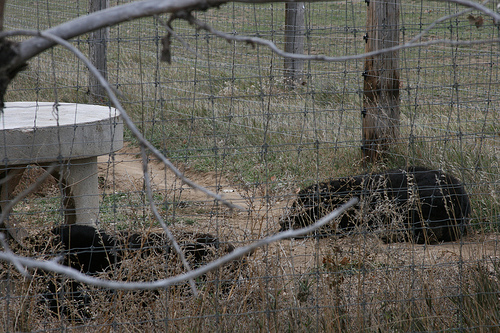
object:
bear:
[276, 164, 473, 246]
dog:
[277, 164, 473, 246]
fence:
[0, 0, 500, 333]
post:
[358, 0, 408, 170]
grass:
[0, 0, 499, 237]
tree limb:
[0, 195, 360, 291]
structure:
[0, 99, 128, 231]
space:
[6, 164, 80, 252]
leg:
[58, 157, 102, 227]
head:
[277, 179, 347, 241]